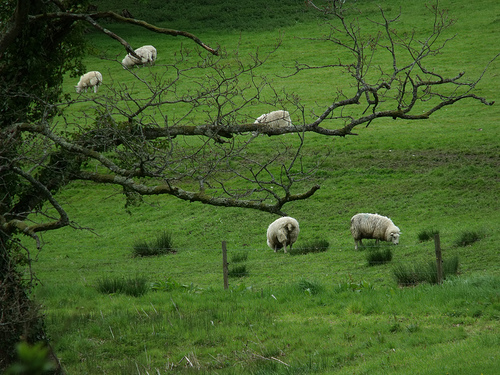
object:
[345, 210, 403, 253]
sheep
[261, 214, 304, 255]
sheep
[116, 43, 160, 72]
sheep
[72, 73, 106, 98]
sheep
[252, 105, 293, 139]
sheep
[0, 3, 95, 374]
tree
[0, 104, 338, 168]
branch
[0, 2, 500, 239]
branch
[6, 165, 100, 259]
branch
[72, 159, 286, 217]
branch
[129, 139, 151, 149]
leaves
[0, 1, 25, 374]
trunk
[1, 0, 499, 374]
prairie [?]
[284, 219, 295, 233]
tail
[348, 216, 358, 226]
tail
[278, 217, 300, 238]
butt end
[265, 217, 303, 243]
wool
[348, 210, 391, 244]
wool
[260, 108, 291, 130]
wool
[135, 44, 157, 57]
wool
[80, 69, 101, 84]
wool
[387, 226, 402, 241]
head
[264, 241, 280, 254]
head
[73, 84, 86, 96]
head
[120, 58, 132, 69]
head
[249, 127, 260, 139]
head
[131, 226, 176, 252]
patch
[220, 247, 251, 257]
patch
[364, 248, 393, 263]
patch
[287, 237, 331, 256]
patch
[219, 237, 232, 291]
post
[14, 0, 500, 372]
ground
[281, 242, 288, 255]
leg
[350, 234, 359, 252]
leg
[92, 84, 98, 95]
leg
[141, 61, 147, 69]
leg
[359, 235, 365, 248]
leg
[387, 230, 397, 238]
ear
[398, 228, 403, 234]
ear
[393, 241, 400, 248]
nose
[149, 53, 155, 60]
'turkerworker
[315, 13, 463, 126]
branchlet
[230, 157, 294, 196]
branchlet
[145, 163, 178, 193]
branchlet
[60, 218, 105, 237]
branchlet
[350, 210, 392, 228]
back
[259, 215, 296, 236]
back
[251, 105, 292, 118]
back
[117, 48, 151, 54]
back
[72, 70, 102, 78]
back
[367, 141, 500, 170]
mud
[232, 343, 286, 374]
grass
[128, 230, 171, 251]
grass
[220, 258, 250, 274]
grass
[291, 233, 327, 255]
grass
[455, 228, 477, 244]
grass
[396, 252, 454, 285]
grass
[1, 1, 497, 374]
meadow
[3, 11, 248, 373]
left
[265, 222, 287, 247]
side